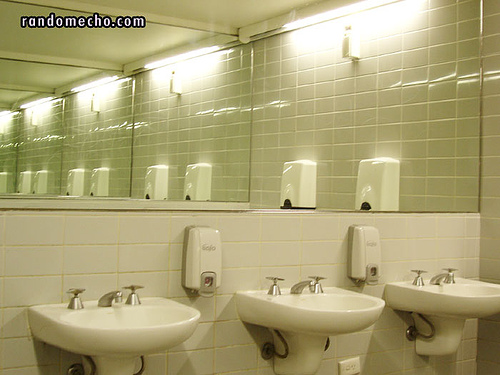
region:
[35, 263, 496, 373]
three white bathroom sinks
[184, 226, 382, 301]
two white soap dispensers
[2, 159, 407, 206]
row of soap dispensers reflected in mirror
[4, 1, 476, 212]
mirror above three sinks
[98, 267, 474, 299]
silver faucets of three sinks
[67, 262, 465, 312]
hot and cold knobs of three sinks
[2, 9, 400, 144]
line of wall lights reflected in mirror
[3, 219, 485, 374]
white tiled wall behind sinks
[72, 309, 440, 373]
silver pipes underneath sink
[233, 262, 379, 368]
white sink in middle of three sinks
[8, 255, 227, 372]
white sink on bathroom wall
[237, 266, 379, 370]
white sink on bathroom wall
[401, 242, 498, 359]
white sink on bathroom wall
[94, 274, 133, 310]
silver faucet on white sink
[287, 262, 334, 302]
silver faucet on white sink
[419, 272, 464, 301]
silver faucet on white sink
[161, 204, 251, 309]
white soap dispenser on wall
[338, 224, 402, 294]
white soap dispenser on wall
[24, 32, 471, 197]
large mirror over sinks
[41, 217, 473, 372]
white tiles on wall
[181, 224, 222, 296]
the soap dispenser on the wall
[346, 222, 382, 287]
the soap dispenser on the wall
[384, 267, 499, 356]
the white bathroom sink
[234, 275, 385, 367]
the white bathroom sink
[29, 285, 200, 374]
the white bathroom sink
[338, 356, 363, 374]
the outlet on the wall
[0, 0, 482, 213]
the bathroom mirror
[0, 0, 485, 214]
the reflection in the mirror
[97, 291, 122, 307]
the water faucet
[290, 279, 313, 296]
the water faucet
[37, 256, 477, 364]
three sinks in the bathroom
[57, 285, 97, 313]
silver faucet handle on sink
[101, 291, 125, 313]
silver spout on sink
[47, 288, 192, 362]
large white sink bowl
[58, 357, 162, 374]
metal wiring tubes below sink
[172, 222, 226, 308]
soap dispenser on wall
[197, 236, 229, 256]
logo on soap dispenser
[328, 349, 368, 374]
small white outlet plate on walal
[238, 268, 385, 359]
white sink on the tile wall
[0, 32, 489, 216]
large mirror on front of wall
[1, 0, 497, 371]
the scene takes place in the bathroom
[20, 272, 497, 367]
the sinks are white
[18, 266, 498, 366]
three sinks in a row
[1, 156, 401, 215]
the hand dryers have a reflection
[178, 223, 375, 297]
the soap dispensers are on the wall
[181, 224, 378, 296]
two hanging soap dispensers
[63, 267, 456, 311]
the sink fixtures are silver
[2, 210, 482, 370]
the wall is tiled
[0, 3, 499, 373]
the bathroom is white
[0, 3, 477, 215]
the mirror has a reflection